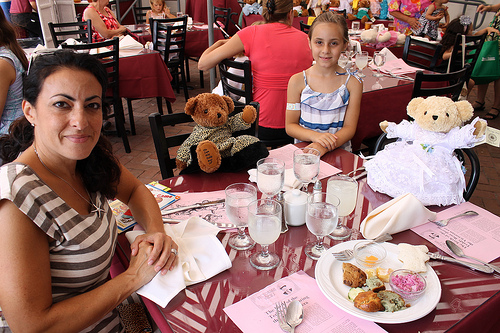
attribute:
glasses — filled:
[246, 196, 283, 273]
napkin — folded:
[358, 190, 441, 241]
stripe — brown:
[66, 225, 105, 258]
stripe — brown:
[11, 169, 114, 330]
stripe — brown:
[36, 202, 79, 242]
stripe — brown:
[48, 227, 116, 284]